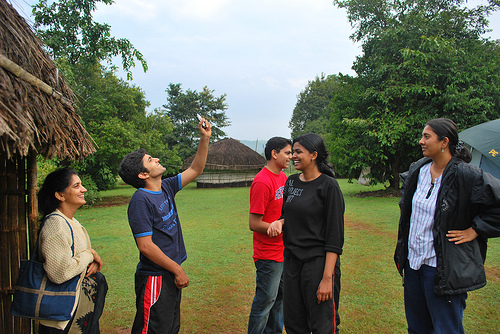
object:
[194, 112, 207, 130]
cellphone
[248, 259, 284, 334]
jeans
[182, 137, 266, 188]
grass hut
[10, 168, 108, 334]
lady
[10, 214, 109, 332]
bag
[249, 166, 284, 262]
shirt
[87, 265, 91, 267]
ring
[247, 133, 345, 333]
people standing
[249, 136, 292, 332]
guy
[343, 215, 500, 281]
path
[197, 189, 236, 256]
grass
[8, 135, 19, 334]
pole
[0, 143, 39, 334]
pole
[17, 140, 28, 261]
pole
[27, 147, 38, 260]
pole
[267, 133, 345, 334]
woman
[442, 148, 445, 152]
earring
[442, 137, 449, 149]
ear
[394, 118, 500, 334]
woman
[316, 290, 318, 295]
ring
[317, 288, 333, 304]
finger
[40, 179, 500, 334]
ground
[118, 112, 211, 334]
guy